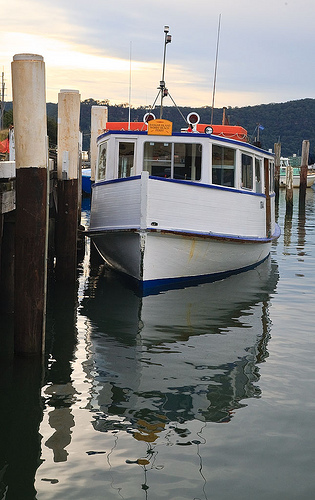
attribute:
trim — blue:
[92, 174, 274, 199]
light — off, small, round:
[143, 112, 155, 127]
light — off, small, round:
[185, 111, 200, 126]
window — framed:
[116, 139, 138, 182]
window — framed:
[141, 140, 206, 185]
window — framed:
[206, 141, 238, 188]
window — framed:
[238, 154, 257, 193]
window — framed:
[94, 144, 109, 180]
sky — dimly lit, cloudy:
[0, 0, 314, 110]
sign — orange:
[143, 116, 171, 135]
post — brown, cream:
[13, 53, 49, 357]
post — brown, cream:
[56, 89, 81, 265]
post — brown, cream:
[301, 141, 313, 182]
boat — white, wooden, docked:
[83, 129, 280, 295]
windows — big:
[97, 140, 274, 194]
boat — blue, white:
[88, 21, 280, 278]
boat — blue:
[97, 26, 281, 291]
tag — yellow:
[146, 119, 171, 135]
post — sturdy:
[9, 42, 83, 336]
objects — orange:
[105, 121, 248, 139]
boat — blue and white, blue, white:
[83, 12, 281, 297]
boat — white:
[86, 126, 286, 378]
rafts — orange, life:
[91, 108, 252, 155]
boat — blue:
[92, 112, 281, 288]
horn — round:
[135, 108, 161, 142]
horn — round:
[185, 108, 203, 133]